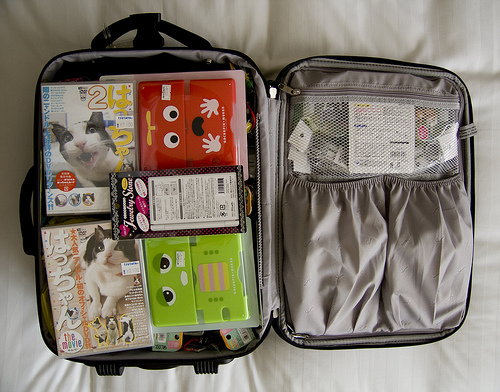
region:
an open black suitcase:
[31, 46, 458, 368]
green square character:
[144, 233, 248, 325]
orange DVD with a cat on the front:
[42, 219, 151, 357]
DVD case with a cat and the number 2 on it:
[41, 78, 137, 220]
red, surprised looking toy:
[136, 81, 238, 168]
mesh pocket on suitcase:
[290, 93, 465, 183]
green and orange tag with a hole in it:
[219, 325, 254, 350]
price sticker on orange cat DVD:
[121, 259, 139, 274]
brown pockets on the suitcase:
[282, 171, 469, 328]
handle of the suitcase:
[20, 168, 37, 249]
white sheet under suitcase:
[0, 1, 498, 390]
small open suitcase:
[16, 14, 474, 377]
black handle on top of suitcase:
[87, 12, 210, 49]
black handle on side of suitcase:
[19, 165, 42, 254]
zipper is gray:
[283, 79, 461, 104]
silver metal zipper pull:
[278, 80, 303, 95]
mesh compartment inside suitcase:
[287, 66, 464, 183]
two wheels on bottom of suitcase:
[193, 358, 225, 372]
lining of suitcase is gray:
[283, 64, 460, 339]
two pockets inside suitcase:
[284, 175, 384, 337]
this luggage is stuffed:
[26, 27, 465, 389]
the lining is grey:
[326, 214, 468, 290]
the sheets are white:
[421, 313, 487, 350]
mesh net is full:
[253, 48, 483, 205]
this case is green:
[131, 209, 269, 313]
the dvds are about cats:
[33, 70, 278, 369]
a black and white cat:
[46, 108, 176, 174]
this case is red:
[120, 82, 271, 213]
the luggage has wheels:
[31, 262, 288, 389]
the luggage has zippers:
[250, 78, 327, 353]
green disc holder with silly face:
[132, 231, 256, 328]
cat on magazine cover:
[51, 224, 133, 361]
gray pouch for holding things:
[287, 162, 450, 350]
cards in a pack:
[107, 166, 242, 243]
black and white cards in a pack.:
[145, 145, 235, 227]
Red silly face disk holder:
[132, 110, 237, 160]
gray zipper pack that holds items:
[70, 43, 458, 325]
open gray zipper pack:
[27, 166, 462, 381]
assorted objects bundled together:
[25, 149, 246, 336]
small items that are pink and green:
[145, 312, 270, 352]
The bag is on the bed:
[1, 0, 496, 388]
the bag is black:
[7, 17, 479, 358]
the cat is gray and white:
[49, 111, 141, 186]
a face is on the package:
[147, 242, 254, 322]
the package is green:
[139, 243, 259, 325]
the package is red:
[144, 89, 245, 166]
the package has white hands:
[182, 89, 237, 164]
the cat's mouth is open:
[57, 133, 113, 183]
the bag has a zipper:
[274, 77, 326, 108]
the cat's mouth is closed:
[86, 224, 133, 274]